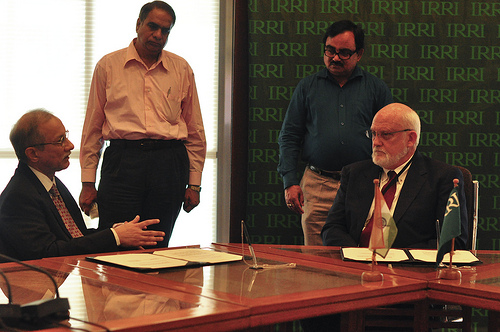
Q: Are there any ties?
A: Yes, there is a tie.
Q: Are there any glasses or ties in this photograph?
A: Yes, there is a tie.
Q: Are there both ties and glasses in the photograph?
A: Yes, there are both a tie and glasses.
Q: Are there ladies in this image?
A: No, there are no ladies.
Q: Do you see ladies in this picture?
A: No, there are no ladies.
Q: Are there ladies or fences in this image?
A: No, there are no ladies or fences.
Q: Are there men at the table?
A: Yes, there is a man at the table.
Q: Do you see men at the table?
A: Yes, there is a man at the table.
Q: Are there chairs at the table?
A: No, there is a man at the table.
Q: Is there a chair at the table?
A: No, there is a man at the table.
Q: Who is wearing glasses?
A: The man is wearing glasses.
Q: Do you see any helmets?
A: No, there are no helmets.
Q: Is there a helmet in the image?
A: No, there are no helmets.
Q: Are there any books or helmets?
A: No, there are no helmets or books.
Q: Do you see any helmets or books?
A: No, there are no helmets or books.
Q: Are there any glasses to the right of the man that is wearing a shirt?
A: Yes, there are glasses to the right of the man.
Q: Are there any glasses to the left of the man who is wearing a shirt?
A: No, the glasses are to the right of the man.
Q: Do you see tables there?
A: Yes, there is a table.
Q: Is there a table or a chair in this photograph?
A: Yes, there is a table.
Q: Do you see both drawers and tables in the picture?
A: No, there is a table but no drawers.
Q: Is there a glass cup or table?
A: Yes, there is a glass table.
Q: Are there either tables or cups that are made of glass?
A: Yes, the table is made of glass.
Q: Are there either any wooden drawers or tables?
A: Yes, there is a wood table.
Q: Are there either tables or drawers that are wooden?
A: Yes, the table is wooden.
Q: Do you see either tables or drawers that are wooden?
A: Yes, the table is wooden.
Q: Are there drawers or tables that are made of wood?
A: Yes, the table is made of wood.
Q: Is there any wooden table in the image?
A: Yes, there is a wood table.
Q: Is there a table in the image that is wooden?
A: Yes, there is a table that is wooden.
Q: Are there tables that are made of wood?
A: Yes, there is a table that is made of wood.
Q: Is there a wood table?
A: Yes, there is a table that is made of wood.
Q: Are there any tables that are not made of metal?
A: Yes, there is a table that is made of wood.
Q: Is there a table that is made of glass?
A: Yes, there is a table that is made of glass.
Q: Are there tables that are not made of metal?
A: Yes, there is a table that is made of glass.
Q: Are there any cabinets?
A: No, there are no cabinets.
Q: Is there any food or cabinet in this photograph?
A: No, there are no cabinets or food.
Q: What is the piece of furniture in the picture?
A: The piece of furniture is a table.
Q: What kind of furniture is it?
A: The piece of furniture is a table.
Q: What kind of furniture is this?
A: This is a table.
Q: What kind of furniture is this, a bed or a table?
A: This is a table.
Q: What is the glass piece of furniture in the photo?
A: The piece of furniture is a table.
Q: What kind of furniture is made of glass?
A: The furniture is a table.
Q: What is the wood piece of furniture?
A: The piece of furniture is a table.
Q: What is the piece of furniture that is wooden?
A: The piece of furniture is a table.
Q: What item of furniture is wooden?
A: The piece of furniture is a table.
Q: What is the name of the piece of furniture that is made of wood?
A: The piece of furniture is a table.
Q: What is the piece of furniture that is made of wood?
A: The piece of furniture is a table.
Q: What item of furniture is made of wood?
A: The piece of furniture is a table.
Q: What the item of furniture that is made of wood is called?
A: The piece of furniture is a table.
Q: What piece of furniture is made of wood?
A: The piece of furniture is a table.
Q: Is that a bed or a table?
A: That is a table.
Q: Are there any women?
A: No, there are no women.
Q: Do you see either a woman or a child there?
A: No, there are no women or children.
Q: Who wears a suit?
A: The man wears a suit.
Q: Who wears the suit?
A: The man wears a suit.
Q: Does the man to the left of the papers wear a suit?
A: Yes, the man wears a suit.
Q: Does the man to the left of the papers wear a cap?
A: No, the man wears a suit.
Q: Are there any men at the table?
A: Yes, there is a man at the table.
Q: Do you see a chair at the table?
A: No, there is a man at the table.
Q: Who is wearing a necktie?
A: The man is wearing a necktie.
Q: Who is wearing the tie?
A: The man is wearing a necktie.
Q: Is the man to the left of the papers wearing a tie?
A: Yes, the man is wearing a tie.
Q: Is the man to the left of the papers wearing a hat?
A: No, the man is wearing a tie.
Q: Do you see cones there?
A: No, there are no cones.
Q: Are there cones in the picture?
A: No, there are no cones.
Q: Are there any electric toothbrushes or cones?
A: No, there are no cones or electric toothbrushes.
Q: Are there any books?
A: No, there are no books.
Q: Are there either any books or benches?
A: No, there are no books or benches.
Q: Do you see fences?
A: No, there are no fences.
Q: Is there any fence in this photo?
A: No, there are no fences.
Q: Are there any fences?
A: No, there are no fences.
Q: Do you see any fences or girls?
A: No, there are no fences or girls.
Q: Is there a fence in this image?
A: No, there are no fences.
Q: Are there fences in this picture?
A: No, there are no fences.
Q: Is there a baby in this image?
A: No, there are no babies.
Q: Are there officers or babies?
A: No, there are no babies or officers.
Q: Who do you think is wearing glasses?
A: The man is wearing glasses.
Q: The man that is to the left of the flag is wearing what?
A: The man is wearing glasses.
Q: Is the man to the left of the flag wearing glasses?
A: Yes, the man is wearing glasses.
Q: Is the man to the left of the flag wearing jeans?
A: No, the man is wearing glasses.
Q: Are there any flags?
A: Yes, there is a flag.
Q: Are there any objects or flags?
A: Yes, there is a flag.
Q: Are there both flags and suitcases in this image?
A: No, there is a flag but no suitcases.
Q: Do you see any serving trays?
A: No, there are no serving trays.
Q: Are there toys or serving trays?
A: No, there are no serving trays or toys.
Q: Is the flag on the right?
A: Yes, the flag is on the right of the image.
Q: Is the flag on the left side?
A: No, the flag is on the right of the image.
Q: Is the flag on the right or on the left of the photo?
A: The flag is on the right of the image.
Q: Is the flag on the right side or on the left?
A: The flag is on the right of the image.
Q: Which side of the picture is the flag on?
A: The flag is on the right of the image.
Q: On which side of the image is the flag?
A: The flag is on the right of the image.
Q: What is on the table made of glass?
A: The flag is on the table.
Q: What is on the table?
A: The flag is on the table.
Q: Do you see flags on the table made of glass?
A: Yes, there is a flag on the table.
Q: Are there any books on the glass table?
A: No, there is a flag on the table.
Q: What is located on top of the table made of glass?
A: The flag is on top of the table.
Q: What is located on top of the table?
A: The flag is on top of the table.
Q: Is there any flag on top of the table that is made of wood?
A: Yes, there is a flag on top of the table.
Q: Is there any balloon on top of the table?
A: No, there is a flag on top of the table.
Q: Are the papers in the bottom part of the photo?
A: Yes, the papers are in the bottom of the image.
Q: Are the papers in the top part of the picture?
A: No, the papers are in the bottom of the image.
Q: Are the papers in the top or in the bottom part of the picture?
A: The papers are in the bottom of the image.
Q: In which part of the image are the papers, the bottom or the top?
A: The papers are in the bottom of the image.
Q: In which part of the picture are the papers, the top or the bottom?
A: The papers are in the bottom of the image.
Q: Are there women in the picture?
A: No, there are no women.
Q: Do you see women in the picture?
A: No, there are no women.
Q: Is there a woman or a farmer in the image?
A: No, there are no women or farmers.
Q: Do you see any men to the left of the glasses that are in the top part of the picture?
A: Yes, there is a man to the left of the glasses.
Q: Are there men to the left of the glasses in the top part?
A: Yes, there is a man to the left of the glasses.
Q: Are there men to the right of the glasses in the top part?
A: No, the man is to the left of the glasses.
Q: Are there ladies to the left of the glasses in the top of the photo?
A: No, there is a man to the left of the glasses.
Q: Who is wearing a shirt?
A: The man is wearing a shirt.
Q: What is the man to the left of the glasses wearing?
A: The man is wearing a shirt.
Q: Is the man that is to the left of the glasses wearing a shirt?
A: Yes, the man is wearing a shirt.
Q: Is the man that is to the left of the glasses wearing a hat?
A: No, the man is wearing a shirt.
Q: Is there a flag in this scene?
A: Yes, there is a flag.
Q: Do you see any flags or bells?
A: Yes, there is a flag.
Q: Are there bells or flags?
A: Yes, there is a flag.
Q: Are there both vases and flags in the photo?
A: No, there is a flag but no vases.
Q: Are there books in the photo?
A: No, there are no books.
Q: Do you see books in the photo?
A: No, there are no books.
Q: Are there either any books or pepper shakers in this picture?
A: No, there are no books or pepper shakers.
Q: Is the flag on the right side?
A: Yes, the flag is on the right of the image.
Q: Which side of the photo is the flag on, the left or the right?
A: The flag is on the right of the image.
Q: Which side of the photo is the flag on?
A: The flag is on the right of the image.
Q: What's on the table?
A: The flag is on the table.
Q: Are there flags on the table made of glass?
A: Yes, there is a flag on the table.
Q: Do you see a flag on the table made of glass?
A: Yes, there is a flag on the table.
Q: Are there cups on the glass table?
A: No, there is a flag on the table.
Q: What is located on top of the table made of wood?
A: The flag is on top of the table.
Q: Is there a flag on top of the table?
A: Yes, there is a flag on top of the table.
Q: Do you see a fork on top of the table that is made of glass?
A: No, there is a flag on top of the table.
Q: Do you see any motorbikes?
A: No, there are no motorbikes.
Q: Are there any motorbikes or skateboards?
A: No, there are no motorbikes or skateboards.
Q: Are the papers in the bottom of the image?
A: Yes, the papers are in the bottom of the image.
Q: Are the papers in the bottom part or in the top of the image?
A: The papers are in the bottom of the image.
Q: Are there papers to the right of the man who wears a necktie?
A: Yes, there are papers to the right of the man.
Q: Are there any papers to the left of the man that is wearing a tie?
A: No, the papers are to the right of the man.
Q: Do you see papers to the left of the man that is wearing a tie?
A: No, the papers are to the right of the man.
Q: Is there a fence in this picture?
A: No, there are no fences.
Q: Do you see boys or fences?
A: No, there are no fences or boys.